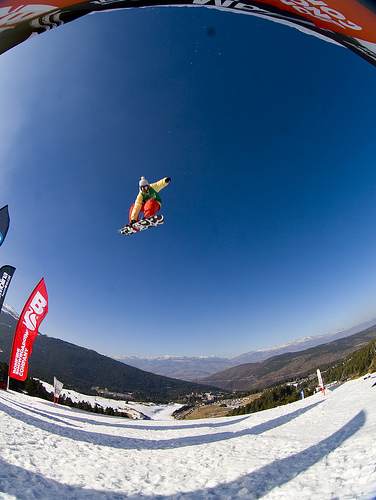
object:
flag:
[5, 276, 48, 389]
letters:
[29, 287, 48, 314]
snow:
[3, 382, 373, 495]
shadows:
[8, 393, 326, 453]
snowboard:
[117, 213, 165, 235]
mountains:
[0, 303, 375, 401]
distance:
[0, 237, 375, 420]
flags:
[0, 0, 375, 66]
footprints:
[205, 448, 303, 497]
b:
[29, 290, 47, 315]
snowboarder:
[116, 174, 172, 236]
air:
[8, 49, 114, 146]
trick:
[116, 175, 171, 236]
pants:
[128, 198, 159, 225]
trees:
[19, 374, 128, 417]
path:
[3, 363, 223, 498]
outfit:
[117, 175, 173, 235]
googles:
[138, 183, 148, 191]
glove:
[165, 176, 171, 182]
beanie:
[138, 174, 150, 186]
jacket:
[127, 176, 169, 220]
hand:
[128, 220, 135, 226]